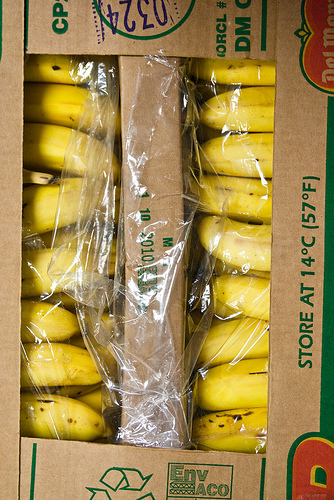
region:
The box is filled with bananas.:
[0, 0, 332, 498]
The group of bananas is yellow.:
[183, 67, 280, 447]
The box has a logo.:
[294, 0, 332, 96]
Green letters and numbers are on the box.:
[295, 173, 319, 371]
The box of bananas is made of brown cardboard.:
[1, 0, 332, 498]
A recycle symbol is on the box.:
[85, 463, 155, 498]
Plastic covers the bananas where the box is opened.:
[22, 58, 272, 451]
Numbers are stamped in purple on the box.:
[88, 0, 180, 45]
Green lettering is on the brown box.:
[206, 0, 271, 61]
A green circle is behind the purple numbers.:
[87, 0, 197, 41]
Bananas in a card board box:
[162, 57, 285, 351]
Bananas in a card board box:
[183, 306, 261, 438]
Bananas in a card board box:
[15, 287, 117, 435]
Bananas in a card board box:
[22, 203, 111, 343]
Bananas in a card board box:
[182, 298, 277, 431]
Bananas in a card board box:
[17, 178, 131, 351]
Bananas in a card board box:
[27, 360, 135, 452]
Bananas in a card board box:
[176, 354, 271, 451]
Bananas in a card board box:
[177, 86, 282, 282]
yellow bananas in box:
[34, 55, 269, 458]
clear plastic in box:
[67, 67, 220, 425]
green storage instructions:
[283, 160, 326, 391]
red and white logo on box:
[294, 1, 331, 94]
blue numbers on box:
[91, 1, 168, 36]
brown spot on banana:
[202, 408, 253, 439]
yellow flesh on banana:
[187, 74, 249, 248]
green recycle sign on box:
[83, 458, 153, 498]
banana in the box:
[189, 407, 265, 449]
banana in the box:
[207, 360, 271, 406]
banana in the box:
[201, 316, 264, 363]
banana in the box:
[16, 386, 106, 439]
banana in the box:
[33, 342, 108, 390]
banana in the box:
[23, 306, 67, 337]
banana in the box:
[199, 219, 261, 274]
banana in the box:
[192, 178, 258, 222]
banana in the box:
[203, 175, 265, 217]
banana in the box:
[200, 137, 268, 178]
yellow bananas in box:
[27, 53, 259, 449]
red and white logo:
[293, 13, 332, 86]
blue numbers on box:
[97, 0, 176, 30]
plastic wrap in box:
[80, 80, 222, 432]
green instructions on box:
[281, 161, 318, 377]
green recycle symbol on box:
[82, 464, 143, 497]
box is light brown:
[296, 312, 321, 437]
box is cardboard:
[268, 368, 311, 423]